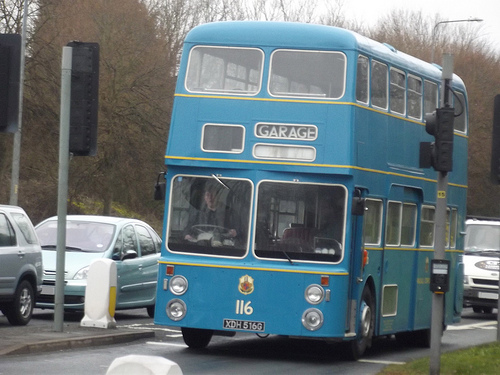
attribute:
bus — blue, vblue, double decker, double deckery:
[173, 11, 419, 337]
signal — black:
[394, 84, 454, 183]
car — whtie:
[36, 200, 160, 284]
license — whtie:
[254, 118, 328, 143]